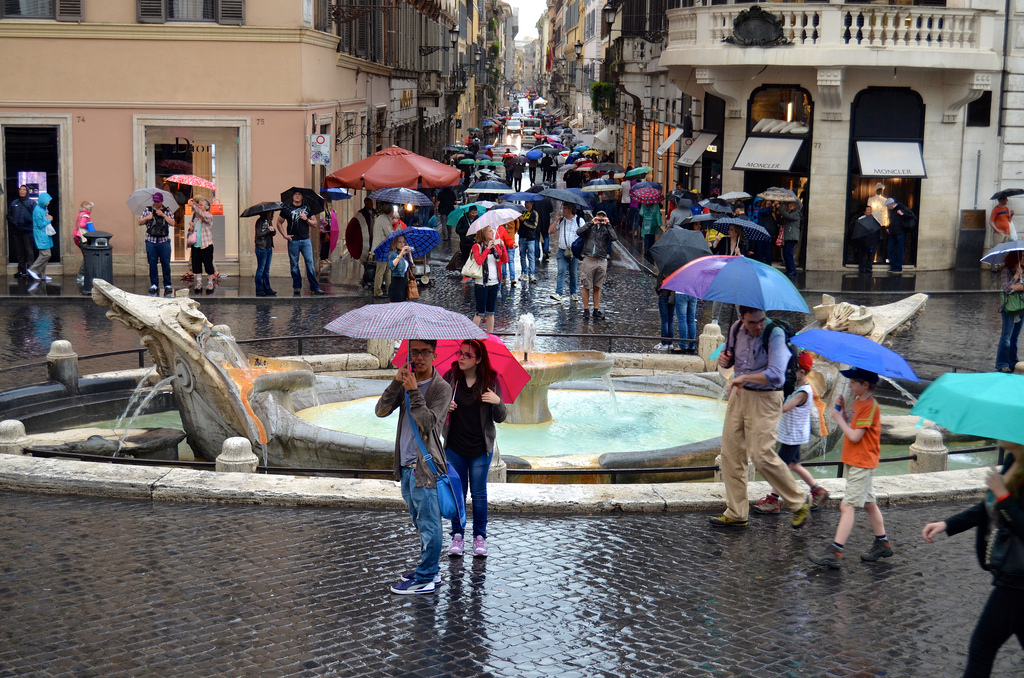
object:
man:
[710, 301, 816, 541]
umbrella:
[651, 251, 818, 323]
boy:
[810, 365, 905, 580]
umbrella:
[777, 324, 928, 387]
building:
[13, 5, 466, 281]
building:
[543, 1, 1018, 270]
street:
[0, 496, 1021, 672]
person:
[785, 353, 820, 518]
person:
[925, 430, 1023, 672]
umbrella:
[321, 139, 468, 191]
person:
[32, 190, 56, 283]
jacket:
[30, 189, 55, 252]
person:
[443, 335, 507, 560]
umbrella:
[384, 325, 532, 401]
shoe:
[383, 571, 438, 595]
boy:
[374, 334, 451, 601]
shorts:
[840, 461, 880, 513]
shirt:
[841, 394, 884, 470]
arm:
[397, 368, 452, 432]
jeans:
[394, 456, 448, 579]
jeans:
[441, 441, 493, 540]